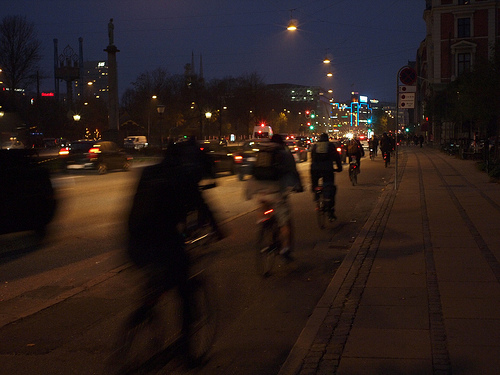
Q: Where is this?
A: This is at the road.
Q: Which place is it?
A: It is a road.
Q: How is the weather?
A: It is clear.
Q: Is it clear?
A: Yes, it is clear.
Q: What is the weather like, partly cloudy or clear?
A: It is clear.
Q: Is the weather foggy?
A: No, it is clear.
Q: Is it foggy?
A: No, it is clear.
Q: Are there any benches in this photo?
A: No, there are no benches.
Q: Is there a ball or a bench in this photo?
A: No, there are no benches or balls.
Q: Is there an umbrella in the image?
A: No, there are no umbrellas.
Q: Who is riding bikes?
A: The people are riding bikes.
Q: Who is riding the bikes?
A: The people are riding bikes.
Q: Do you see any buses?
A: No, there are no buses.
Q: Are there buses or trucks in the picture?
A: No, there are no buses or trucks.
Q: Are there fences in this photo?
A: No, there are no fences.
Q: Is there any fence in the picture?
A: No, there are no fences.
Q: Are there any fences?
A: No, there are no fences.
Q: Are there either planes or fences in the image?
A: No, there are no fences or planes.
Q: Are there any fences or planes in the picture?
A: No, there are no fences or planes.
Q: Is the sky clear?
A: Yes, the sky is clear.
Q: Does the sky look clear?
A: Yes, the sky is clear.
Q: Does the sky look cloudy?
A: No, the sky is clear.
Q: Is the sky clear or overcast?
A: The sky is clear.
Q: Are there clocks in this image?
A: No, there are no clocks.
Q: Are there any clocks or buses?
A: No, there are no clocks or buses.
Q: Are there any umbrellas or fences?
A: No, there are no fences or umbrellas.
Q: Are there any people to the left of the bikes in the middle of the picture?
A: Yes, there are people to the left of the bikes.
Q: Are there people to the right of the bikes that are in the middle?
A: No, the people are to the left of the bicycles.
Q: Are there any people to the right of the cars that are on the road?
A: Yes, there are people to the right of the cars.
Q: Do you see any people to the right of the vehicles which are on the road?
A: Yes, there are people to the right of the cars.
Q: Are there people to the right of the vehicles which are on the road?
A: Yes, there are people to the right of the cars.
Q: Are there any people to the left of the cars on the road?
A: No, the people are to the right of the cars.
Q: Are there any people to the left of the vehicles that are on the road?
A: No, the people are to the right of the cars.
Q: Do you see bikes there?
A: Yes, there are bikes.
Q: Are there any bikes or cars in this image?
A: Yes, there are bikes.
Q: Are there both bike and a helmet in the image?
A: No, there are bikes but no helmets.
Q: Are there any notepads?
A: No, there are no notepads.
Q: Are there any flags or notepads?
A: No, there are no notepads or flags.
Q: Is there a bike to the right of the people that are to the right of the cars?
A: Yes, there are bikes to the right of the people.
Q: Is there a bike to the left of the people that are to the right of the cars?
A: No, the bikes are to the right of the people.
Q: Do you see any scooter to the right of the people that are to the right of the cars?
A: No, there are bikes to the right of the people.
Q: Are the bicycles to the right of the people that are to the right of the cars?
A: Yes, the bicycles are to the right of the people.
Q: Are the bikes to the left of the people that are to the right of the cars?
A: No, the bikes are to the right of the people.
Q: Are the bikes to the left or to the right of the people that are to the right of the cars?
A: The bikes are to the right of the people.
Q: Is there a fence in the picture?
A: No, there are no fences.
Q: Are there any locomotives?
A: No, there are no locomotives.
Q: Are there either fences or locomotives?
A: No, there are no locomotives or fences.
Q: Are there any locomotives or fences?
A: No, there are no locomotives or fences.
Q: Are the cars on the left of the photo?
A: Yes, the cars are on the left of the image.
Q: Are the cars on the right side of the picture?
A: No, the cars are on the left of the image.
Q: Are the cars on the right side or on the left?
A: The cars are on the left of the image.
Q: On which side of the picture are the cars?
A: The cars are on the left of the image.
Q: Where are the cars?
A: The cars are on the road.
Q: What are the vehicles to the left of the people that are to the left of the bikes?
A: The vehicles are cars.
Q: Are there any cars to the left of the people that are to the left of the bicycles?
A: Yes, there are cars to the left of the people.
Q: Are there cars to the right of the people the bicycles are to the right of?
A: No, the cars are to the left of the people.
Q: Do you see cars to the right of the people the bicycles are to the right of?
A: No, the cars are to the left of the people.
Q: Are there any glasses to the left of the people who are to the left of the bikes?
A: No, there are cars to the left of the people.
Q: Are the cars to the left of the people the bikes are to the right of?
A: Yes, the cars are to the left of the people.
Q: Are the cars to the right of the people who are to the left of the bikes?
A: No, the cars are to the left of the people.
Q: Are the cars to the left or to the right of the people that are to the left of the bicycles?
A: The cars are to the left of the people.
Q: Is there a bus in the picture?
A: No, there are no buses.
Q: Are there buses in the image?
A: No, there are no buses.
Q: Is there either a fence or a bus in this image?
A: No, there are no buses or fences.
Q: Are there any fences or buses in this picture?
A: No, there are no buses or fences.